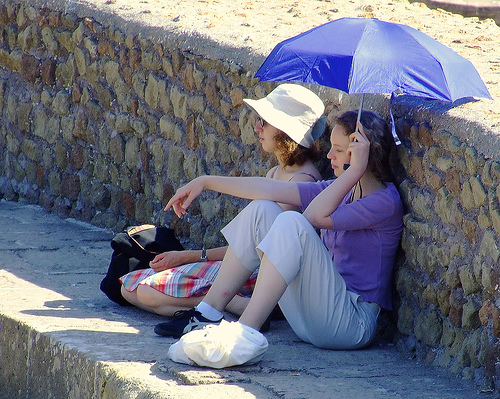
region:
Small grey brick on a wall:
[457, 178, 478, 208]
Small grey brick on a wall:
[431, 157, 448, 179]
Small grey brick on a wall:
[190, 65, 207, 91]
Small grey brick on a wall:
[186, 93, 204, 110]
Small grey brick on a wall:
[104, 130, 121, 165]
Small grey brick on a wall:
[118, 134, 135, 166]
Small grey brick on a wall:
[135, 136, 150, 166]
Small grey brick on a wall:
[146, 136, 171, 177]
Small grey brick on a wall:
[163, 141, 190, 178]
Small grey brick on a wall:
[101, 181, 136, 223]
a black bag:
[112, 230, 157, 265]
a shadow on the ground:
[76, 329, 122, 359]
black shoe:
[152, 321, 187, 332]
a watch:
[195, 247, 212, 262]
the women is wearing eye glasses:
[251, 117, 266, 127]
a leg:
[256, 274, 278, 296]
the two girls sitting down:
[117, 81, 402, 348]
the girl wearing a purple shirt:
[158, 108, 402, 344]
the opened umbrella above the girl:
[252, 17, 494, 172]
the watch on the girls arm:
[197, 245, 207, 260]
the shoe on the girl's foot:
[153, 307, 223, 336]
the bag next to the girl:
[99, 222, 185, 307]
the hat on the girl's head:
[241, 83, 325, 149]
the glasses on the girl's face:
[252, 115, 264, 127]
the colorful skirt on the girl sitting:
[117, 255, 257, 297]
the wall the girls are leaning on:
[0, 0, 498, 393]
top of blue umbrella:
[267, 23, 477, 113]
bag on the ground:
[162, 323, 269, 372]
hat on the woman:
[234, 86, 317, 148]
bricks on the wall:
[52, 80, 180, 147]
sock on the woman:
[190, 299, 221, 321]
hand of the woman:
[155, 178, 204, 220]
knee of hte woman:
[273, 222, 313, 254]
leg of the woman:
[252, 274, 287, 324]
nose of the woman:
[251, 123, 263, 134]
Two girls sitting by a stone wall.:
[94, 83, 408, 372]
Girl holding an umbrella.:
[230, 5, 487, 325]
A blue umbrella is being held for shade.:
[250, 10, 488, 177]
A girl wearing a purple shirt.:
[291, 159, 403, 301]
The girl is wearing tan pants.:
[217, 188, 375, 350]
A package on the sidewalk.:
[167, 309, 274, 368]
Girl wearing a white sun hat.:
[231, 68, 329, 170]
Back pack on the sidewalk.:
[86, 201, 188, 311]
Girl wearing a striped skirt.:
[109, 240, 227, 300]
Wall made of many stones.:
[7, 56, 184, 193]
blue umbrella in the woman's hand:
[251, 12, 498, 172]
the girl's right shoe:
[152, 307, 224, 339]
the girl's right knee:
[244, 196, 279, 229]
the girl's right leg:
[199, 240, 249, 317]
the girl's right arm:
[208, 176, 298, 202]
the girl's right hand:
[159, 171, 207, 221]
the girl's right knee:
[113, 280, 138, 305]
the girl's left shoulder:
[365, 183, 400, 225]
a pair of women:
[105, 72, 420, 387]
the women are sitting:
[108, 0, 425, 396]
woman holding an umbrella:
[242, 22, 488, 225]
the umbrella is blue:
[243, 14, 480, 187]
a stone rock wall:
[14, 11, 199, 200]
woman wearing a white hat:
[233, 80, 328, 155]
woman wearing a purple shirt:
[296, 170, 405, 307]